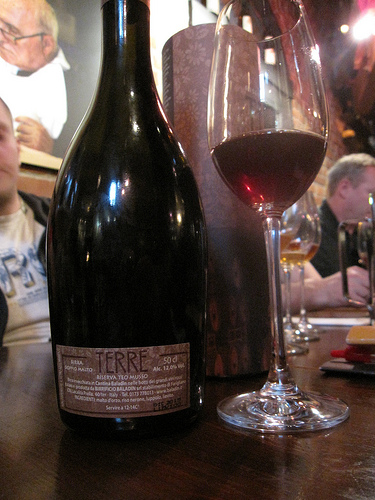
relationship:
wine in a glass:
[207, 130, 329, 213] [205, 0, 356, 438]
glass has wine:
[205, 0, 356, 438] [213, 130, 325, 215]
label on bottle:
[50, 340, 193, 421] [37, 0, 215, 428]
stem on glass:
[261, 216, 298, 392] [195, 0, 358, 430]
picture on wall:
[1, 1, 103, 159] [1, 2, 359, 232]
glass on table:
[205, 0, 356, 438] [3, 302, 358, 498]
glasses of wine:
[275, 188, 327, 361] [284, 250, 304, 264]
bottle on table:
[37, 0, 215, 428] [3, 302, 358, 498]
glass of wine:
[205, 0, 356, 438] [213, 130, 325, 215]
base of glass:
[216, 381, 351, 442] [205, 0, 356, 438]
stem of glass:
[261, 216, 298, 392] [205, 0, 356, 438]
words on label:
[64, 370, 190, 410] [50, 340, 206, 418]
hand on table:
[314, 262, 363, 307] [3, 302, 358, 498]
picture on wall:
[1, 1, 114, 179] [2, 1, 363, 258]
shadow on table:
[59, 409, 301, 498] [3, 302, 358, 498]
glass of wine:
[195, 0, 358, 430] [213, 130, 325, 215]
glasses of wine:
[275, 188, 327, 361] [283, 233, 298, 266]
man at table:
[299, 150, 361, 301] [3, 302, 358, 498]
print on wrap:
[172, 29, 214, 127] [158, 23, 275, 375]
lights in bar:
[352, 13, 374, 39] [0, 0, 371, 495]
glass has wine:
[205, 0, 356, 438] [207, 130, 329, 213]